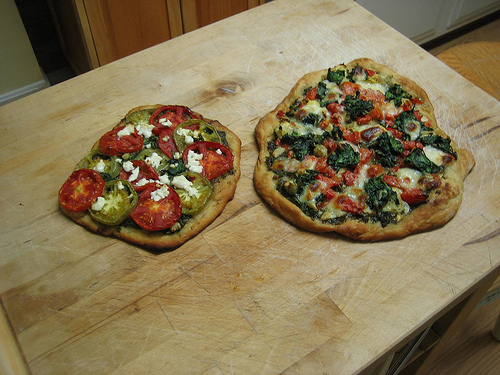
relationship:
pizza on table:
[53, 101, 242, 254] [0, 0, 499, 374]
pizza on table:
[251, 57, 478, 245] [0, 0, 499, 374]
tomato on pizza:
[175, 119, 223, 155] [53, 101, 242, 254]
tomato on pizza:
[184, 141, 234, 179] [53, 101, 242, 254]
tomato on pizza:
[172, 171, 213, 214] [53, 101, 242, 254]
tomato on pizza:
[129, 184, 181, 230] [53, 101, 242, 254]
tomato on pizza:
[88, 178, 138, 222] [53, 101, 242, 254]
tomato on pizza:
[59, 169, 106, 210] [53, 101, 242, 254]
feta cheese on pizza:
[185, 146, 205, 174] [53, 101, 242, 254]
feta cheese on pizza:
[143, 152, 164, 168] [53, 101, 242, 254]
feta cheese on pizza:
[90, 196, 105, 211] [53, 101, 242, 254]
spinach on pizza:
[378, 131, 405, 164] [251, 57, 478, 245]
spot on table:
[197, 69, 248, 100] [0, 0, 499, 374]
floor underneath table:
[413, 20, 499, 374] [0, 0, 499, 374]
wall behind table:
[0, 0, 47, 102] [0, 0, 499, 374]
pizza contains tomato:
[53, 101, 242, 254] [175, 119, 223, 155]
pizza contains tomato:
[53, 101, 242, 254] [184, 141, 234, 179]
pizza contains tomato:
[53, 101, 242, 254] [172, 171, 213, 214]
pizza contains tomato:
[53, 101, 242, 254] [129, 184, 181, 230]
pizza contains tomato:
[53, 101, 242, 254] [88, 178, 138, 222]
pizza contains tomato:
[53, 101, 242, 254] [59, 169, 106, 210]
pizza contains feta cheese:
[53, 101, 242, 254] [185, 146, 205, 174]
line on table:
[233, 296, 261, 337] [0, 0, 499, 374]